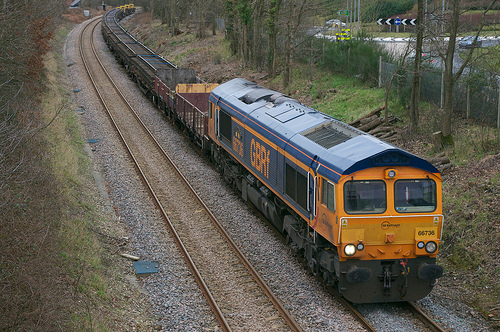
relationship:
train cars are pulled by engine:
[105, 0, 186, 114] [167, 74, 450, 304]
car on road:
[428, 31, 498, 51] [299, 3, 488, 96]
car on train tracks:
[428, 31, 498, 51] [296, 16, 363, 38]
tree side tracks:
[422, 8, 491, 149] [81, 28, 226, 220]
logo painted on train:
[246, 137, 271, 179] [202, 65, 452, 308]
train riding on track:
[202, 65, 452, 308] [247, 202, 446, 330]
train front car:
[202, 65, 452, 308] [95, 5, 198, 112]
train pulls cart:
[202, 65, 452, 308] [170, 74, 219, 146]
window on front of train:
[342, 178, 383, 213] [264, 125, 442, 263]